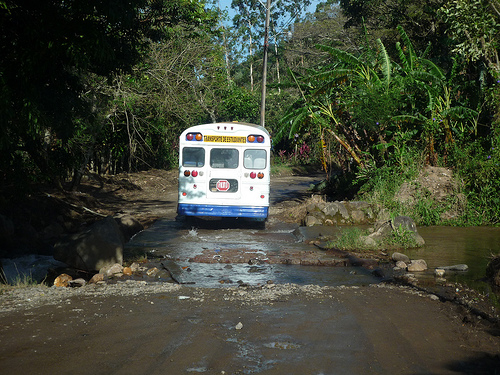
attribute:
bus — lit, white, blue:
[166, 117, 285, 220]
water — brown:
[3, 184, 499, 339]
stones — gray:
[4, 215, 500, 301]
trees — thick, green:
[1, 1, 499, 243]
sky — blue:
[198, 2, 343, 68]